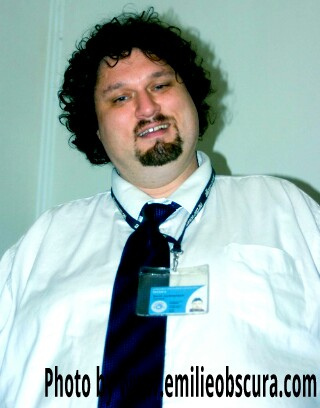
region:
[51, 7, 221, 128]
The man had dark hair.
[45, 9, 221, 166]
The mans hair is black.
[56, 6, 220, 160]
The mans hair is long.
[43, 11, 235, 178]
The mans hair is messy.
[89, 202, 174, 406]
The man is wearing a necktie.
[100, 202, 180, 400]
The necktie is blue and black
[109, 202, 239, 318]
The man is wearing a lanyard.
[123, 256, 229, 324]
The lanyard holds the mans identification.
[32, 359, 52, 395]
The letter is black.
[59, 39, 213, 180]
face of the man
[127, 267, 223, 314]
name tag on shirt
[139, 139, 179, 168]
beard of the man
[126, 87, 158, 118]
nose of the man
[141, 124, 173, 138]
mouth of the man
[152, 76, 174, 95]
eye of the man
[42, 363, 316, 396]
logo for the photographer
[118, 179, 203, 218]
collar of the shirt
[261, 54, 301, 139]
the wall is green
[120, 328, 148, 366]
the tie is blue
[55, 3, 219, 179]
Head of a man smiling at the camera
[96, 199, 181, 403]
Dark blue tie worn by a person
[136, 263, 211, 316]
Identification card of the person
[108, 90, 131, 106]
Right eye of the person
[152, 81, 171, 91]
left eye of the person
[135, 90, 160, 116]
Nose of the person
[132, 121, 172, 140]
Mouth of the person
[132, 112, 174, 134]
Black moustache of the person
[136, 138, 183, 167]
Black beard of the person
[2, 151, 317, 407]
White shirt worn by the person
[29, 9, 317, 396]
This is a person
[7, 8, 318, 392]
This is a person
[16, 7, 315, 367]
This is a person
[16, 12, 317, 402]
This is a person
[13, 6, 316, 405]
This is a person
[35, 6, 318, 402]
This is a person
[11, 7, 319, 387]
This is a person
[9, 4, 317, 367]
This is a person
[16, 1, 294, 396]
This is a person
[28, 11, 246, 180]
the man with curly hair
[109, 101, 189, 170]
the man with beard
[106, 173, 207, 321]
the name tag hanging from neck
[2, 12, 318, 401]
the man wearing tie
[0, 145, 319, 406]
man wearing a white shirt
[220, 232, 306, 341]
the pocket on the shirt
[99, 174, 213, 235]
the lanyard of the name tag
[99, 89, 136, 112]
eye of the man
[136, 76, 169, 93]
eye of the man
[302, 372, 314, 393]
A letter on the picture.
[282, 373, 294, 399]
A letter on the picture.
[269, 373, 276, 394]
A letter on the picture.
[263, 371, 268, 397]
A letter on the picture.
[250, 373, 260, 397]
A letter on the picture.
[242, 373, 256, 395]
A letter on the picture.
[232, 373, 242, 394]
A letter on the picture.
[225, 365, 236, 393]
A letter on the picture.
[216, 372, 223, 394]
A letter on the picture.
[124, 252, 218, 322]
plastic name badge holder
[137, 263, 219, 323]
plastic name badge holder